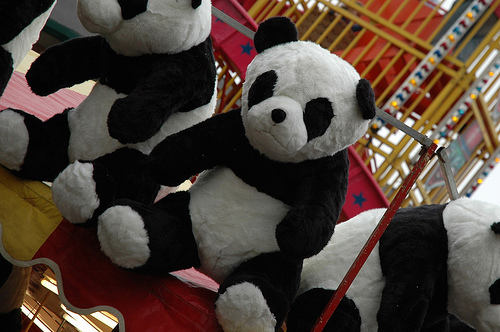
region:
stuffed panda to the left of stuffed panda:
[1, 1, 219, 178]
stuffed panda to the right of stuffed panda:
[91, 15, 380, 329]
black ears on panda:
[254, 16, 296, 54]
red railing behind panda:
[214, 3, 258, 75]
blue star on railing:
[236, 40, 255, 55]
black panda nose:
[271, 108, 288, 119]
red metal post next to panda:
[297, 142, 437, 330]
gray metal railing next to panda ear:
[374, 107, 429, 147]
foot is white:
[97, 205, 147, 270]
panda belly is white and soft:
[190, 167, 284, 277]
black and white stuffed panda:
[165, 13, 347, 310]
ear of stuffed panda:
[361, 79, 386, 126]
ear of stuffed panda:
[243, 10, 308, 52]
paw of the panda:
[105, 100, 166, 163]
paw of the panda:
[261, 217, 336, 256]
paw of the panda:
[213, 281, 268, 327]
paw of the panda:
[102, 208, 160, 269]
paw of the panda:
[61, 160, 95, 225]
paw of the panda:
[0, 113, 35, 174]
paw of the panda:
[18, 59, 71, 106]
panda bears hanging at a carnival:
[2, 0, 498, 329]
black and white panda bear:
[0, 1, 490, 327]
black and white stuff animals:
[2, 0, 495, 330]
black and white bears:
[4, 2, 490, 329]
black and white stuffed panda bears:
[1, 0, 498, 329]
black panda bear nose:
[267, 105, 291, 127]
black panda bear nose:
[352, 75, 384, 120]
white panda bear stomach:
[181, 171, 299, 267]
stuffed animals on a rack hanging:
[0, 3, 498, 329]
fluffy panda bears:
[1, 0, 496, 330]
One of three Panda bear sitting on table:
[93, 17, 379, 330]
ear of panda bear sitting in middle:
[244, 15, 298, 53]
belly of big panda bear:
[193, 173, 287, 269]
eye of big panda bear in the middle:
[305, 98, 333, 138]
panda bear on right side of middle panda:
[307, 197, 493, 328]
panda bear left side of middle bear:
[2, 1, 214, 219]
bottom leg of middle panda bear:
[213, 255, 299, 330]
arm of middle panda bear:
[147, 106, 237, 187]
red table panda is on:
[7, 182, 209, 330]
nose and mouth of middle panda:
[245, 94, 308, 156]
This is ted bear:
[104, 9, 380, 326]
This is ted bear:
[287, 132, 495, 323]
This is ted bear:
[1, 0, 241, 229]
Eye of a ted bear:
[300, 88, 335, 148]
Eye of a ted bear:
[227, 62, 286, 112]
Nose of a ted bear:
[264, 100, 291, 130]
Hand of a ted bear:
[261, 163, 354, 266]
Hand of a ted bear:
[138, 110, 243, 190]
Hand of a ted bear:
[104, 60, 181, 155]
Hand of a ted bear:
[16, 28, 126, 100]